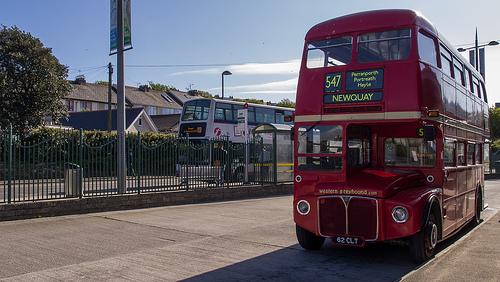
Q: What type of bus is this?
A: A double decker bus.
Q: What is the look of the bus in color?
A: Red.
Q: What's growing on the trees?
A: Leaves.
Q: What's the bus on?
A: Road.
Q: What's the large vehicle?
A: Bus.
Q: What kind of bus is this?
A: Double decker.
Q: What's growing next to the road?
A: Hedge bushes.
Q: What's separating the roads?
A: Metal fence.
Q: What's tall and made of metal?
A: Pole.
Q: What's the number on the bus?
A: 547.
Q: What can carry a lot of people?
A: Bus.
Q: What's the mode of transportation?
A: Bus.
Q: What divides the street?
A: Gate.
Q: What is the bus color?
A: Red.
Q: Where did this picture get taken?
A: It was taken on the sidewalk.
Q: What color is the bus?
A: The bus is red.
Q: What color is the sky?
A: The sky is blue.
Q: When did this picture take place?
A: This picture took place in the day time.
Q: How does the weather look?
A: The weather looks nice and sunny.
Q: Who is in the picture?
A: Nobody is in the picture.